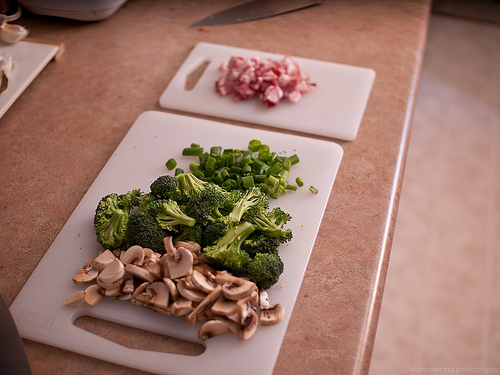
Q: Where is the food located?
A: Cutting board.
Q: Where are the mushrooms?
A: Next to broccoli.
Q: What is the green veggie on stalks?
A: Broccoli.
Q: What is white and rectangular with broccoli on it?
A: Cutting board.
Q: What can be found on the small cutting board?
A: Meat.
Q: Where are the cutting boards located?
A: Tan countertop.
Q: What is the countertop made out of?
A: Marble.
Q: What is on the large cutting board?
A: Cut and diced veggies.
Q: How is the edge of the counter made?
A: Rounded edge.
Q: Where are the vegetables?
A: On the chopping boards.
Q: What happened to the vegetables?
A: They were chopped.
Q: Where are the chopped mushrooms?
A: On the chopping board by the broccoli.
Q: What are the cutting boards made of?
A: Plastic.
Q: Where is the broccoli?
A: By the mushrooms.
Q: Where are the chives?
A: Next to the broccoli.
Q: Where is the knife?
A: Above the cutting boards.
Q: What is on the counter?
A: Cutting boards with vegetables.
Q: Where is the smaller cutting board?
A: Above the larger one with the mushrooms, broccoli and chives.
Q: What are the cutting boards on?
A: Countertop.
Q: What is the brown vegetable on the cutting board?
A: Mushrooms.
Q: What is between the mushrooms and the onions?
A: Broccoli.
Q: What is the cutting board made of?
A: Plastic.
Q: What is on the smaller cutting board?
A: Meat.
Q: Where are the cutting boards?
A: On the counter.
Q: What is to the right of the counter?
A: The floor.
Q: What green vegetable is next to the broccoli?
A: Onions.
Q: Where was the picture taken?
A: In a kitchen.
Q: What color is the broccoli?
A: Green.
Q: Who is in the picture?
A: There are no people in the picture.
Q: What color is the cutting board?
A: White.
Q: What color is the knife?
A: Silver.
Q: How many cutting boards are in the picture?
A: Two.